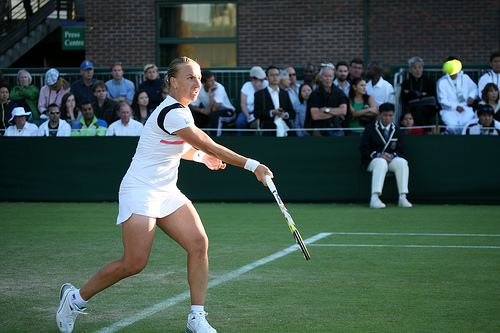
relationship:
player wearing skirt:
[51, 55, 279, 333] [112, 182, 192, 223]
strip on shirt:
[160, 137, 186, 145] [122, 90, 194, 192]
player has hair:
[51, 55, 279, 333] [167, 50, 199, 84]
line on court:
[115, 298, 157, 331] [30, 195, 484, 315]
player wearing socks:
[51, 55, 279, 333] [188, 303, 204, 315]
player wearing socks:
[51, 55, 279, 333] [82, 282, 85, 301]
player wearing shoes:
[51, 55, 279, 333] [183, 301, 217, 331]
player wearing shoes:
[51, 55, 279, 333] [53, 278, 92, 331]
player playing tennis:
[51, 55, 279, 333] [12, 133, 483, 316]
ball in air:
[442, 42, 468, 82] [39, 10, 475, 258]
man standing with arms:
[308, 63, 352, 138] [311, 102, 345, 123]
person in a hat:
[5, 100, 36, 135] [11, 105, 30, 123]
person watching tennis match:
[255, 66, 295, 129] [20, 136, 483, 312]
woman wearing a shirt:
[350, 71, 374, 120] [351, 100, 363, 115]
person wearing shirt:
[34, 60, 81, 115] [39, 79, 69, 114]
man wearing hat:
[73, 55, 106, 102] [75, 58, 97, 73]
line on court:
[95, 215, 328, 329] [4, 191, 497, 328]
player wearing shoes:
[51, 55, 279, 333] [42, 285, 217, 331]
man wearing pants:
[361, 101, 416, 210] [368, 151, 416, 198]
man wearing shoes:
[361, 101, 416, 210] [366, 193, 421, 213]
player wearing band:
[51, 45, 281, 330] [234, 149, 258, 173]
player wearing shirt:
[51, 45, 281, 330] [122, 90, 194, 192]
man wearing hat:
[73, 60, 106, 102] [78, 58, 102, 78]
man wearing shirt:
[308, 63, 352, 144] [298, 83, 358, 125]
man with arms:
[308, 63, 352, 144] [306, 101, 361, 121]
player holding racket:
[51, 55, 279, 333] [253, 163, 336, 277]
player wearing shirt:
[51, 55, 279, 333] [128, 95, 206, 200]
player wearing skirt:
[51, 55, 279, 333] [107, 168, 207, 231]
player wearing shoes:
[51, 55, 279, 333] [53, 279, 223, 330]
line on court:
[115, 298, 157, 331] [4, 191, 497, 328]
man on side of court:
[361, 98, 428, 210] [4, 191, 497, 328]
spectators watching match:
[6, 53, 498, 137] [14, 47, 498, 329]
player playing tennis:
[51, 55, 279, 333] [42, 44, 327, 329]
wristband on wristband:
[236, 157, 268, 178] [236, 157, 268, 178]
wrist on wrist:
[191, 146, 208, 166] [191, 144, 211, 170]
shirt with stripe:
[124, 93, 197, 193] [155, 100, 185, 136]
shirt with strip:
[124, 93, 197, 193] [160, 138, 186, 145]